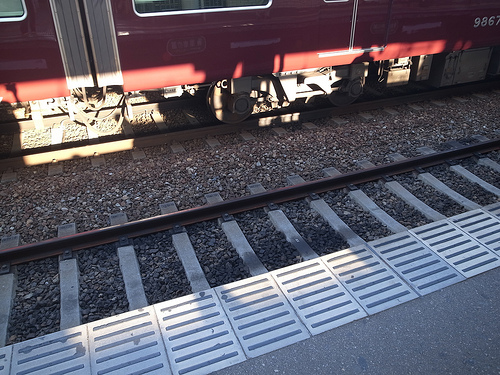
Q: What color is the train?
A: Red.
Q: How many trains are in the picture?
A: One.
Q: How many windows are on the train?
A: Two.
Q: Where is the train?
A: On the tracks.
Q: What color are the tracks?
A: Black.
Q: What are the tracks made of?
A: Metal.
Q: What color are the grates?
A: Silver.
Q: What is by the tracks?
A: Gravel.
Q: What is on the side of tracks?
A: Metal.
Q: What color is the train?
A: Red.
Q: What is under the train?
A: Tracks.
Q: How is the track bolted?
A: Ties.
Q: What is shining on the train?
A: Sunlight.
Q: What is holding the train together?
A: Connectors.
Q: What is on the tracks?
A: Train.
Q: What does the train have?
A: Windows.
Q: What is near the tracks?
A: Platform.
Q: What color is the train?
A: Red.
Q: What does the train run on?
A: Tracks.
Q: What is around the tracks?
A: Gravel.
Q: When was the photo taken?
A: During the daytime.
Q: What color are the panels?
A: Silver.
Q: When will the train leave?
A: There is no way to know this.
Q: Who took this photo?
A: A photographer.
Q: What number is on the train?
A: 9867.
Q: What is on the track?
A: A train.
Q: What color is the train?
A: Red.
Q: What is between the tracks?
A: Pebbles.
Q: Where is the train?
A: On the tracks.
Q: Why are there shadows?
A: The sun is shining.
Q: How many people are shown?
A: Zero.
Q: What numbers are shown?
A: 9867.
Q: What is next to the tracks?
A: The platform.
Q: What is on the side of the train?
A: Windows.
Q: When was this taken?
A: Daytime.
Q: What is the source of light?
A: Sunlight.